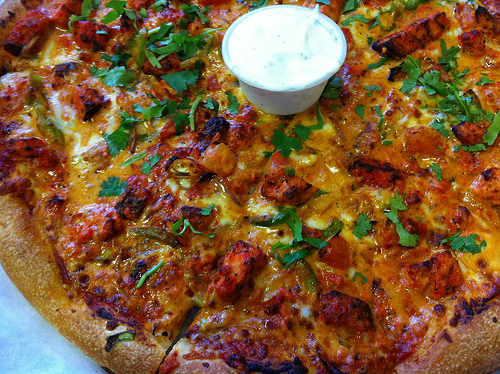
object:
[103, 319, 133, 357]
vegetable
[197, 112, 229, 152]
burnt piece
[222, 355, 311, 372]
burn area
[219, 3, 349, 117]
container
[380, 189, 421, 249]
garnish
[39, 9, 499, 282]
cheese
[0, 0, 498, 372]
pizza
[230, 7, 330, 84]
dip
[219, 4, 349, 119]
bowl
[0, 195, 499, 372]
crust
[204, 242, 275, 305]
sauce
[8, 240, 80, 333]
crust on the pizza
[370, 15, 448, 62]
burnt piece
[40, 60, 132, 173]
cheese on the pizza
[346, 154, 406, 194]
piece of cilantro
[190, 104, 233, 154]
burnt piece near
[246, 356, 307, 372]
burn area near the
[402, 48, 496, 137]
piece of green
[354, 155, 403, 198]
buffalo chicken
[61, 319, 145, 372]
crust on a pizza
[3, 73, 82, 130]
piece of buffalo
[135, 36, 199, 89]
buffalo chicken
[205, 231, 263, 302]
piece of buffalo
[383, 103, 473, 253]
covered in toppings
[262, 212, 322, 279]
torn green seasoning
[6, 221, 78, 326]
brown crust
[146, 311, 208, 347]
cut made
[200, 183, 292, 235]
cheese on the pizza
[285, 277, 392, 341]
meat topping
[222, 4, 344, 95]
sauce on the edges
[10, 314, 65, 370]
white surface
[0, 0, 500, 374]
pizza and dip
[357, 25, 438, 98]
burned toppings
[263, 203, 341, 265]
green parsley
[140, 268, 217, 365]
pizza cut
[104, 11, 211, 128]
chopped parsley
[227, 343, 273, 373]
blackened pizza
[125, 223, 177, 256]
green pepper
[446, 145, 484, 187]
red sauce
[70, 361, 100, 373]
white thing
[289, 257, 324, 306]
green thing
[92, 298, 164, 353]
burned part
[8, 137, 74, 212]
red sauce on pizza